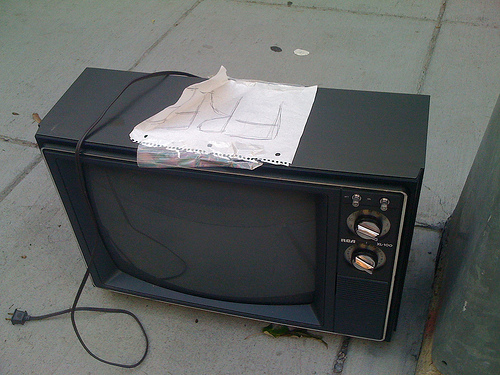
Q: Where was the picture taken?
A: On a sidewalk.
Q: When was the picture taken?
A: Daytime.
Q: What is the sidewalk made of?
A: Cement.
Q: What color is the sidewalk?
A: Gray.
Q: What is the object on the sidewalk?
A: A TV.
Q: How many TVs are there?
A: One.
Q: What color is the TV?
A: Black.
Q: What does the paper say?
A: FREE.